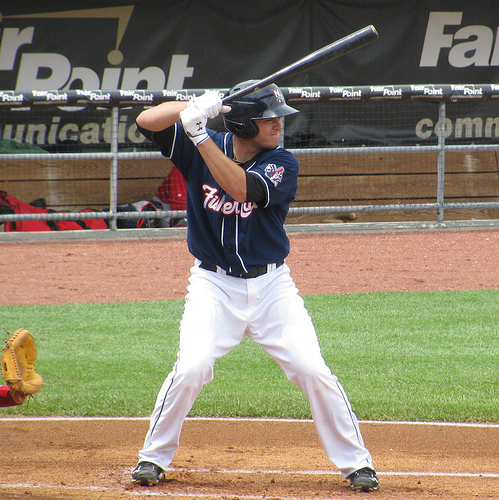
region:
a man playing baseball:
[128, 73, 380, 495]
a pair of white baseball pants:
[139, 259, 366, 476]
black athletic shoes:
[131, 459, 377, 494]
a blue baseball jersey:
[154, 116, 301, 276]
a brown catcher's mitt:
[0, 330, 47, 392]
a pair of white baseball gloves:
[181, 88, 230, 143]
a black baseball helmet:
[221, 76, 299, 136]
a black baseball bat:
[219, 26, 381, 127]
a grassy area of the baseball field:
[1, 287, 495, 421]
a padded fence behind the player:
[0, 84, 498, 224]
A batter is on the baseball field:
[58, 37, 403, 497]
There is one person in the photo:
[118, 94, 391, 499]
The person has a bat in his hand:
[105, 51, 393, 499]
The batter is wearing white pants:
[125, 61, 410, 464]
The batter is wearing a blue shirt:
[142, 88, 377, 349]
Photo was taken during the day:
[64, 48, 451, 403]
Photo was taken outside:
[65, 31, 420, 487]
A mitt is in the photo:
[0, 300, 141, 429]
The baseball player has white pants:
[139, 35, 453, 412]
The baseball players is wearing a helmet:
[147, 26, 369, 264]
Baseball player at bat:
[130, 79, 381, 491]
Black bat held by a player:
[221, 21, 378, 102]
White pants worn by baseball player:
[135, 261, 371, 469]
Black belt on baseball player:
[195, 256, 288, 273]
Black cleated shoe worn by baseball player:
[126, 458, 158, 480]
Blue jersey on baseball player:
[138, 123, 297, 267]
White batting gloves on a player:
[176, 92, 222, 144]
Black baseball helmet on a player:
[220, 75, 294, 136]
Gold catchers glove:
[0, 329, 43, 397]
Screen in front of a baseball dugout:
[1, 81, 497, 223]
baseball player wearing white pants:
[172, 265, 353, 465]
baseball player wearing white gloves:
[168, 84, 227, 151]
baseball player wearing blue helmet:
[220, 65, 306, 129]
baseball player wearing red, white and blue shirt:
[137, 116, 305, 268]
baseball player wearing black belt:
[201, 260, 291, 291]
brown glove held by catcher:
[9, 320, 56, 410]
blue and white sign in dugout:
[12, 16, 135, 149]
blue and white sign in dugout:
[403, 12, 494, 151]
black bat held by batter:
[212, 17, 380, 106]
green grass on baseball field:
[343, 299, 490, 394]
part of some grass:
[395, 332, 448, 380]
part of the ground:
[241, 439, 283, 488]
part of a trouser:
[304, 391, 347, 442]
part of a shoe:
[135, 469, 156, 498]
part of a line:
[145, 397, 164, 429]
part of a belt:
[243, 267, 264, 282]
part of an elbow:
[222, 171, 251, 221]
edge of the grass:
[413, 399, 454, 433]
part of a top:
[261, 198, 286, 229]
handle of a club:
[235, 58, 279, 102]